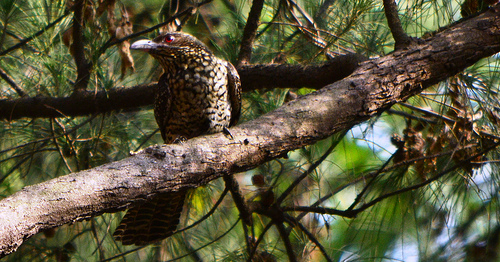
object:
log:
[0, 3, 493, 260]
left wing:
[151, 74, 173, 130]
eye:
[161, 31, 182, 45]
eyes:
[161, 34, 179, 43]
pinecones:
[377, 119, 497, 170]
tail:
[109, 174, 192, 260]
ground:
[371, 169, 403, 196]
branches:
[256, 56, 350, 90]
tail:
[103, 178, 208, 250]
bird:
[111, 207, 194, 247]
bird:
[165, 63, 224, 126]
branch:
[0, 85, 71, 122]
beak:
[125, 37, 162, 53]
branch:
[304, 192, 377, 225]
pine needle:
[405, 170, 422, 260]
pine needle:
[362, 121, 383, 155]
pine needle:
[486, 147, 494, 248]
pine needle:
[374, 195, 394, 260]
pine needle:
[432, 0, 440, 30]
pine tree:
[1, 0, 498, 260]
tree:
[5, 1, 494, 251]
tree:
[54, 19, 429, 219]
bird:
[193, 73, 215, 93]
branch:
[449, 149, 497, 178]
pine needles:
[203, 185, 218, 262]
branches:
[51, 73, 103, 106]